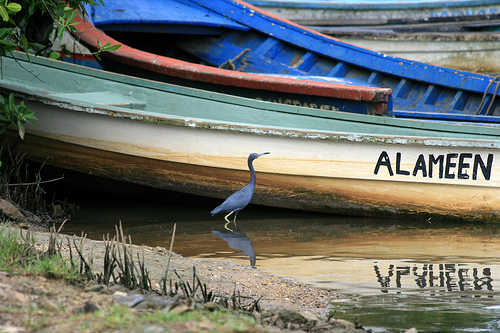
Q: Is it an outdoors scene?
A: Yes, it is outdoors.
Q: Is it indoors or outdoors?
A: It is outdoors.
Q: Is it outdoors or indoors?
A: It is outdoors.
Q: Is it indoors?
A: No, it is outdoors.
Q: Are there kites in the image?
A: No, there are no kites.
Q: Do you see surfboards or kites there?
A: No, there are no kites or surfboards.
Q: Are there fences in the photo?
A: No, there are no fences.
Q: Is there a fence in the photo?
A: No, there are no fences.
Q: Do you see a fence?
A: No, there are no fences.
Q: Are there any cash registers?
A: No, there are no cash registers.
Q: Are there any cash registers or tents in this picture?
A: No, there are no cash registers or tents.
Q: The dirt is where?
A: The dirt is on the shore.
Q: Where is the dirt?
A: The dirt is on the shore.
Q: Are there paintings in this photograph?
A: No, there are no paintings.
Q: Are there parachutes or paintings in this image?
A: No, there are no paintings or parachutes.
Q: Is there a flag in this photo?
A: No, there are no flags.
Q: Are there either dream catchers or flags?
A: No, there are no flags or dream catchers.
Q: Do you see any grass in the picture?
A: Yes, there is grass.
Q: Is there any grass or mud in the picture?
A: Yes, there is grass.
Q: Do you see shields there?
A: No, there are no shields.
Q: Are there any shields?
A: No, there are no shields.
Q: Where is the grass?
A: The grass is on the shore.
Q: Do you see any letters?
A: Yes, there are letters.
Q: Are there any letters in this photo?
A: Yes, there are letters.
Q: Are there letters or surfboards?
A: Yes, there are letters.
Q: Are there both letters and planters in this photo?
A: No, there are letters but no planters.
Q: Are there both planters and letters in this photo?
A: No, there are letters but no planters.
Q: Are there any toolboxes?
A: No, there are no toolboxes.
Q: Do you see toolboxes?
A: No, there are no toolboxes.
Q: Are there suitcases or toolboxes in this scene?
A: No, there are no toolboxes or suitcases.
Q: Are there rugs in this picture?
A: No, there are no rugs.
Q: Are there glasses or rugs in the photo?
A: No, there are no rugs or glasses.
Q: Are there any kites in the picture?
A: No, there are no kites.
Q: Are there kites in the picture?
A: No, there are no kites.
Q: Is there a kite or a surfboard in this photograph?
A: No, there are no kites or surfboards.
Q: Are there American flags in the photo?
A: No, there are no American flags.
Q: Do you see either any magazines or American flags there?
A: No, there are no American flags or magazines.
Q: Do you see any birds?
A: Yes, there is a bird.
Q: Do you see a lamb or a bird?
A: Yes, there is a bird.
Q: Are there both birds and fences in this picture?
A: No, there is a bird but no fences.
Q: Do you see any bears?
A: No, there are no bears.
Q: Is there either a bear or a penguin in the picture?
A: No, there are no bears or penguins.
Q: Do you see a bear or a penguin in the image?
A: No, there are no bears or penguins.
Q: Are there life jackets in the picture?
A: No, there are no life jackets.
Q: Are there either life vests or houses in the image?
A: No, there are no life vests or houses.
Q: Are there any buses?
A: No, there are no buses.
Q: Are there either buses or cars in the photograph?
A: No, there are no buses or cars.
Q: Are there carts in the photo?
A: No, there are no carts.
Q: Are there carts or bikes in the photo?
A: No, there are no carts or bikes.